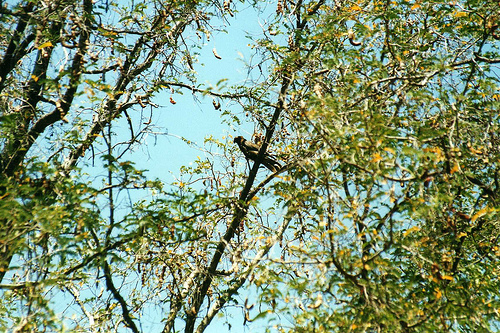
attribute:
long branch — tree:
[180, 0, 330, 331]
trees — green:
[328, 21, 493, 208]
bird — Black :
[229, 137, 287, 173]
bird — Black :
[187, 124, 307, 190]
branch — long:
[181, 71, 308, 331]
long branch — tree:
[356, 47, 498, 126]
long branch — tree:
[296, 102, 496, 199]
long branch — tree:
[296, 119, 367, 289]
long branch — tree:
[157, 72, 279, 108]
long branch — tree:
[0, 226, 153, 288]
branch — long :
[297, 86, 483, 211]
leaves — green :
[346, 67, 481, 165]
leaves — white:
[358, 117, 460, 193]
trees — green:
[31, 12, 433, 329]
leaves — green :
[281, 83, 438, 199]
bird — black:
[233, 135, 284, 177]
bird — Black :
[229, 134, 279, 178]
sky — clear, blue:
[167, 107, 217, 132]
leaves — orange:
[0, 0, 499, 331]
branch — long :
[4, 0, 94, 175]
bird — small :
[233, 135, 280, 172]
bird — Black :
[221, 133, 297, 173]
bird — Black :
[228, 133, 285, 173]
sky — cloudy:
[0, 2, 498, 332]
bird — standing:
[231, 134, 284, 175]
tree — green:
[34, 10, 199, 217]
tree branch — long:
[176, 5, 313, 330]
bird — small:
[227, 129, 292, 184]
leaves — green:
[296, 100, 422, 202]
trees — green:
[4, 0, 498, 330]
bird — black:
[227, 132, 299, 194]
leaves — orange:
[307, 87, 448, 199]